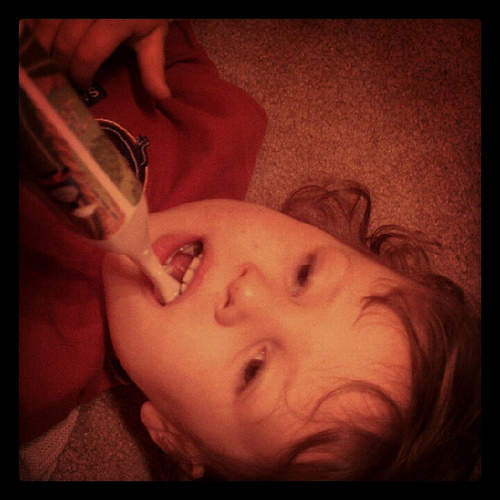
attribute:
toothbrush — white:
[40, 81, 172, 298]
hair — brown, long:
[388, 288, 485, 455]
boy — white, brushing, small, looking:
[33, 20, 499, 493]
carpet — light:
[251, 32, 493, 199]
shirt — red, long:
[18, 21, 218, 185]